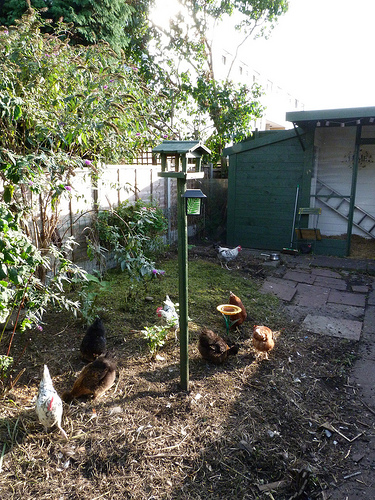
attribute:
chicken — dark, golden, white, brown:
[250, 320, 279, 353]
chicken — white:
[34, 368, 64, 415]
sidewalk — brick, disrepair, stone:
[250, 253, 373, 333]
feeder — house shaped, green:
[152, 133, 205, 182]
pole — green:
[176, 180, 193, 395]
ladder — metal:
[310, 178, 374, 236]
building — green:
[222, 108, 373, 256]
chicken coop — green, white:
[226, 127, 314, 248]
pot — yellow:
[217, 299, 243, 330]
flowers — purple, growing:
[147, 264, 174, 285]